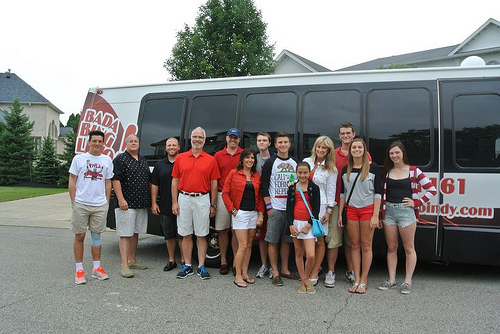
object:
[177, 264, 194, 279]
sneaker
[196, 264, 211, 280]
sneaker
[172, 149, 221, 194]
shirt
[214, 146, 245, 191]
shirt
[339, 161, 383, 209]
shirt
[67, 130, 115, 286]
boy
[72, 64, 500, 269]
bus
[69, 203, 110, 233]
shorts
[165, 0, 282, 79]
tall tree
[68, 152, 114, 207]
shirt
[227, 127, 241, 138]
hat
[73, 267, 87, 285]
sneakers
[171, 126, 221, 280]
man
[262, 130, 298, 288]
man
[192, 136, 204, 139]
eyeglasses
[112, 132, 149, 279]
man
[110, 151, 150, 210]
shirt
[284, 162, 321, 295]
girl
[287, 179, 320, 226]
sweater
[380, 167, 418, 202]
tank top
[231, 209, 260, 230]
shorts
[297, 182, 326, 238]
handbag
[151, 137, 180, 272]
man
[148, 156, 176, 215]
shirt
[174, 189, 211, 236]
shorts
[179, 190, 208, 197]
belt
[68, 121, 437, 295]
group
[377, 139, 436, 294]
girl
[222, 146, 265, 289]
girl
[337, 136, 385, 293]
girl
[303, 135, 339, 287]
girl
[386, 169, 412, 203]
black tank-top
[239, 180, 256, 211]
black tank-top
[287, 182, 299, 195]
shoulder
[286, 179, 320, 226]
jacket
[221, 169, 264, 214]
red jacket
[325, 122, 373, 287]
man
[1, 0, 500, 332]
picture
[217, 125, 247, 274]
man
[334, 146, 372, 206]
shirt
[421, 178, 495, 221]
writing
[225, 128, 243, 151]
head